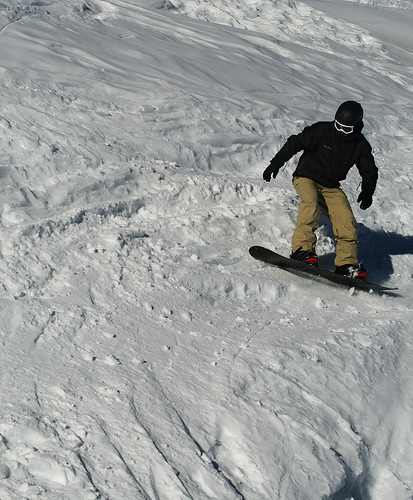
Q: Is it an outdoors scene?
A: Yes, it is outdoors.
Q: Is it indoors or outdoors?
A: It is outdoors.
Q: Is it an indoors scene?
A: No, it is outdoors.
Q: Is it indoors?
A: No, it is outdoors.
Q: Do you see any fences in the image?
A: No, there are no fences.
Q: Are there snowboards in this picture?
A: Yes, there is a snowboard.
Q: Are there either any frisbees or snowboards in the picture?
A: Yes, there is a snowboard.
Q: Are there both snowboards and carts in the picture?
A: No, there is a snowboard but no carts.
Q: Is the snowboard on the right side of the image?
A: Yes, the snowboard is on the right of the image.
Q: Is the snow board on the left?
A: No, the snow board is on the right of the image.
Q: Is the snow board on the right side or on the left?
A: The snow board is on the right of the image.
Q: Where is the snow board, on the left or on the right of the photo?
A: The snow board is on the right of the image.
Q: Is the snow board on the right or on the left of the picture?
A: The snow board is on the right of the image.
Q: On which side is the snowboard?
A: The snowboard is on the right of the image.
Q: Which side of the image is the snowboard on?
A: The snowboard is on the right of the image.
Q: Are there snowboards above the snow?
A: Yes, there is a snowboard above the snow.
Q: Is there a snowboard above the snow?
A: Yes, there is a snowboard above the snow.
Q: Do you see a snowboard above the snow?
A: Yes, there is a snowboard above the snow.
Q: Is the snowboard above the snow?
A: Yes, the snowboard is above the snow.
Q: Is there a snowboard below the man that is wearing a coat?
A: Yes, there is a snowboard below the man.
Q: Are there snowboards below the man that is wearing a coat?
A: Yes, there is a snowboard below the man.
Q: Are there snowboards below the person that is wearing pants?
A: Yes, there is a snowboard below the man.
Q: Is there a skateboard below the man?
A: No, there is a snowboard below the man.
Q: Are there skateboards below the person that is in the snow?
A: No, there is a snowboard below the man.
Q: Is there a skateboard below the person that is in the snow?
A: No, there is a snowboard below the man.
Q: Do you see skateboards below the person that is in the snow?
A: No, there is a snowboard below the man.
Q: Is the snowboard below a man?
A: Yes, the snowboard is below a man.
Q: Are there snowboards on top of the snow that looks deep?
A: Yes, there is a snowboard on top of the snow.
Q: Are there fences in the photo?
A: No, there are no fences.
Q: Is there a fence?
A: No, there are no fences.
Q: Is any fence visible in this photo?
A: No, there are no fences.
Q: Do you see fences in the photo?
A: No, there are no fences.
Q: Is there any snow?
A: Yes, there is snow.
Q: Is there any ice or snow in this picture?
A: Yes, there is snow.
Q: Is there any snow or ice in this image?
A: Yes, there is snow.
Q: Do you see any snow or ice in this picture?
A: Yes, there is snow.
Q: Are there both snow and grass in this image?
A: No, there is snow but no grass.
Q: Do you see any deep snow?
A: Yes, there is deep snow.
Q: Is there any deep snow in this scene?
A: Yes, there is deep snow.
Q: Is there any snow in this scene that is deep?
A: Yes, there is snow that is deep.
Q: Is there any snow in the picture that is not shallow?
A: Yes, there is deep snow.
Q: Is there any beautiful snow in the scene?
A: Yes, there is beautiful snow.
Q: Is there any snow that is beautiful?
A: Yes, there is snow that is beautiful.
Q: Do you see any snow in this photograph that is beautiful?
A: Yes, there is snow that is beautiful.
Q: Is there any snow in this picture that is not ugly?
A: Yes, there is beautiful snow.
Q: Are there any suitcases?
A: No, there are no suitcases.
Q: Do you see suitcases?
A: No, there are no suitcases.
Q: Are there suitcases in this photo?
A: No, there are no suitcases.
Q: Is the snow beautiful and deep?
A: Yes, the snow is beautiful and deep.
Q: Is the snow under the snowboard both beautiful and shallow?
A: No, the snow is beautiful but deep.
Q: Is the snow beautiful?
A: Yes, the snow is beautiful.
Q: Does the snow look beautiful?
A: Yes, the snow is beautiful.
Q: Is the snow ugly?
A: No, the snow is beautiful.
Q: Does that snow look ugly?
A: No, the snow is beautiful.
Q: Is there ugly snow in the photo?
A: No, there is snow but it is beautiful.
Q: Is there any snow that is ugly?
A: No, there is snow but it is beautiful.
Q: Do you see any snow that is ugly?
A: No, there is snow but it is beautiful.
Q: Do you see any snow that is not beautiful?
A: No, there is snow but it is beautiful.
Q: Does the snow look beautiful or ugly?
A: The snow is beautiful.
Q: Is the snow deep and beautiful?
A: Yes, the snow is deep and beautiful.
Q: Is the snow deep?
A: Yes, the snow is deep.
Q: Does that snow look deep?
A: Yes, the snow is deep.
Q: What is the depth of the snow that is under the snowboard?
A: The snow is deep.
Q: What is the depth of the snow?
A: The snow is deep.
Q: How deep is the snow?
A: The snow is deep.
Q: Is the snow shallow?
A: No, the snow is deep.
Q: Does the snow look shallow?
A: No, the snow is deep.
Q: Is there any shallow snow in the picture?
A: No, there is snow but it is deep.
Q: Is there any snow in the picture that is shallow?
A: No, there is snow but it is deep.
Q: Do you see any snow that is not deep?
A: No, there is snow but it is deep.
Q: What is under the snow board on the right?
A: The snow is under the snowboard.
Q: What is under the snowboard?
A: The snow is under the snowboard.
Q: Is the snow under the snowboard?
A: Yes, the snow is under the snowboard.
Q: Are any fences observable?
A: No, there are no fences.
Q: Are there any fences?
A: No, there are no fences.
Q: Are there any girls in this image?
A: No, there are no girls.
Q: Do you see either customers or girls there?
A: No, there are no girls or customers.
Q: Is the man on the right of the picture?
A: Yes, the man is on the right of the image.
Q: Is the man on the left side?
A: No, the man is on the right of the image.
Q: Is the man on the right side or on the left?
A: The man is on the right of the image.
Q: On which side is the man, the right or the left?
A: The man is on the right of the image.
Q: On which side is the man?
A: The man is on the right of the image.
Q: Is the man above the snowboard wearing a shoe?
A: Yes, the man is wearing a shoe.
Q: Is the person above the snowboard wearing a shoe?
A: Yes, the man is wearing a shoe.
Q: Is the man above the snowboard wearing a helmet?
A: No, the man is wearing a shoe.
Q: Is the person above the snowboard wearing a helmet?
A: No, the man is wearing a shoe.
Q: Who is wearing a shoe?
A: The man is wearing a shoe.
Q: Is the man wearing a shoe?
A: Yes, the man is wearing a shoe.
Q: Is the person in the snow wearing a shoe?
A: Yes, the man is wearing a shoe.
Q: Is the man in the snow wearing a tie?
A: No, the man is wearing a shoe.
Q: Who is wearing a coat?
A: The man is wearing a coat.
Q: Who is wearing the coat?
A: The man is wearing a coat.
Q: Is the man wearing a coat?
A: Yes, the man is wearing a coat.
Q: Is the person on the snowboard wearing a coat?
A: Yes, the man is wearing a coat.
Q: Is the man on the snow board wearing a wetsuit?
A: No, the man is wearing a coat.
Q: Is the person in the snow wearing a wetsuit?
A: No, the man is wearing a coat.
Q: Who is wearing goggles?
A: The man is wearing goggles.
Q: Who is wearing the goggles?
A: The man is wearing goggles.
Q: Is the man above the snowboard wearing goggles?
A: Yes, the man is wearing goggles.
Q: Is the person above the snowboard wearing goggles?
A: Yes, the man is wearing goggles.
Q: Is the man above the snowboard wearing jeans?
A: No, the man is wearing goggles.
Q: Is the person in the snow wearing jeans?
A: No, the man is wearing goggles.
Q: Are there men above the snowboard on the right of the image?
A: Yes, there is a man above the snowboard.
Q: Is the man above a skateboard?
A: No, the man is above the snowboard.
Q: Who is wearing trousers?
A: The man is wearing trousers.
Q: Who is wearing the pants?
A: The man is wearing trousers.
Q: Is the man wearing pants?
A: Yes, the man is wearing pants.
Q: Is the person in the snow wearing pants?
A: Yes, the man is wearing pants.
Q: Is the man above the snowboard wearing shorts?
A: No, the man is wearing pants.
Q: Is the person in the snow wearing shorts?
A: No, the man is wearing pants.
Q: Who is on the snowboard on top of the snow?
A: The man is on the snowboard.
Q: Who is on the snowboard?
A: The man is on the snowboard.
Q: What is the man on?
A: The man is on the snowboard.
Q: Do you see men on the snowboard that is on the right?
A: Yes, there is a man on the snow board.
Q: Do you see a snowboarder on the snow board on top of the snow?
A: No, there is a man on the snowboard.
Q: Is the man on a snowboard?
A: Yes, the man is on a snowboard.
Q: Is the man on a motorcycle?
A: No, the man is on a snowboard.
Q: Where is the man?
A: The man is in the snow.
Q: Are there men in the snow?
A: Yes, there is a man in the snow.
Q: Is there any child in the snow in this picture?
A: No, there is a man in the snow.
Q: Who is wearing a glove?
A: The man is wearing a glove.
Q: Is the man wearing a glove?
A: Yes, the man is wearing a glove.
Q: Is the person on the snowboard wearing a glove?
A: Yes, the man is wearing a glove.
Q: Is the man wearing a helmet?
A: No, the man is wearing a glove.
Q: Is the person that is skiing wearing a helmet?
A: No, the man is wearing a glove.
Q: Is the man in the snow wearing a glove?
A: Yes, the man is wearing a glove.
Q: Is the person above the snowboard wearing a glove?
A: Yes, the man is wearing a glove.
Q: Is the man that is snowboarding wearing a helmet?
A: No, the man is wearing a glove.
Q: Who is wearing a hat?
A: The man is wearing a hat.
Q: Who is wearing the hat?
A: The man is wearing a hat.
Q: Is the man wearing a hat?
A: Yes, the man is wearing a hat.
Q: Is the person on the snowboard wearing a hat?
A: Yes, the man is wearing a hat.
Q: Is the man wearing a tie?
A: No, the man is wearing a hat.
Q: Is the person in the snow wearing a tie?
A: No, the man is wearing a hat.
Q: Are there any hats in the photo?
A: Yes, there is a hat.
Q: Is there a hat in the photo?
A: Yes, there is a hat.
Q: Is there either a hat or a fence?
A: Yes, there is a hat.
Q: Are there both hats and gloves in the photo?
A: Yes, there are both a hat and gloves.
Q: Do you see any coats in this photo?
A: Yes, there is a coat.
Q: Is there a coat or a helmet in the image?
A: Yes, there is a coat.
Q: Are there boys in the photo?
A: No, there are no boys.